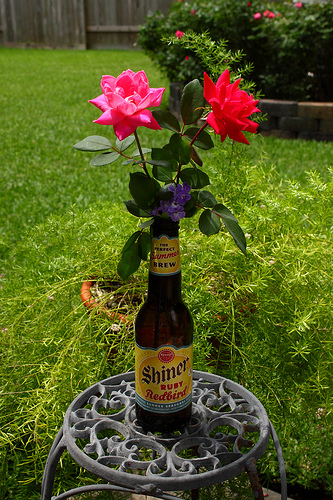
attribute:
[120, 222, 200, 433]
beer bottle — brown, shiny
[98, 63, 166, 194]
flower — pink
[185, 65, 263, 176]
flower — red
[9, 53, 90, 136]
grass — green, short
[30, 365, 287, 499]
stool — gray, metal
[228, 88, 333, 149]
planter pot — clay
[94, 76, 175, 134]
rose — pink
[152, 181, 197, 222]
flowers — tiny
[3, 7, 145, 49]
fence — wooden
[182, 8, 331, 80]
rosebush — large